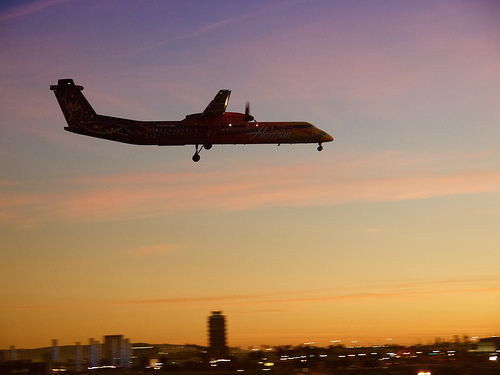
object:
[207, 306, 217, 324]
pillar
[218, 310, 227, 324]
pillar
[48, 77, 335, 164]
airplane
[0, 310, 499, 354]
skyline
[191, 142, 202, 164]
landing gear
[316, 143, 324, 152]
landing gear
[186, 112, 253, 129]
engine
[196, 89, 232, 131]
wing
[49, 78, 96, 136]
tail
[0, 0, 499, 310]
sky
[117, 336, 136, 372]
skyscraper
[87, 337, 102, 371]
skyscraper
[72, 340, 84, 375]
skyscraper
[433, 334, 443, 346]
tree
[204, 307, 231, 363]
building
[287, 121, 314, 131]
cockpit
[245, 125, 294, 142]
word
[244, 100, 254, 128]
propellar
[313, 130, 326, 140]
stripe